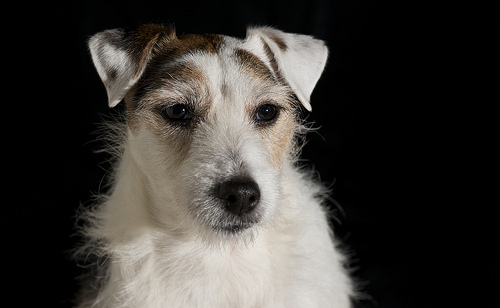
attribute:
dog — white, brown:
[68, 15, 368, 305]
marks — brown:
[148, 59, 197, 88]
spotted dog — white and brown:
[80, 17, 357, 305]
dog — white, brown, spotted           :
[79, 21, 355, 302]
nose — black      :
[217, 178, 260, 214]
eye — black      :
[160, 100, 196, 123]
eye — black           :
[249, 100, 284, 123]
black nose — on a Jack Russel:
[214, 176, 261, 215]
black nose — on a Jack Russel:
[218, 175, 260, 215]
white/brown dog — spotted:
[81, 16, 361, 303]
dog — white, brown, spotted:
[38, 23, 388, 278]